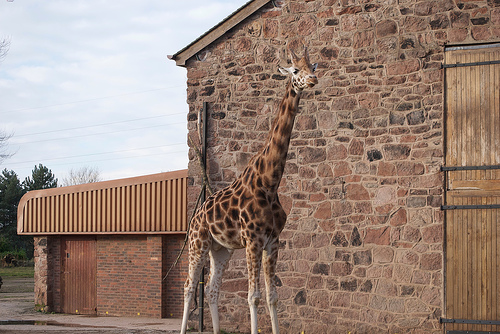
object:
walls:
[169, 0, 500, 334]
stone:
[353, 92, 382, 109]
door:
[440, 46, 499, 333]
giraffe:
[180, 45, 328, 334]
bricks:
[147, 309, 159, 312]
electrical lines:
[0, 162, 186, 189]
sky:
[0, 1, 249, 189]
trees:
[1, 130, 111, 268]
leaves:
[1, 164, 66, 266]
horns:
[286, 97, 299, 115]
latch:
[440, 162, 499, 175]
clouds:
[0, 0, 244, 187]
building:
[13, 0, 500, 334]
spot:
[289, 88, 298, 99]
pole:
[196, 100, 213, 333]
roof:
[167, 0, 265, 65]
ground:
[0, 281, 185, 334]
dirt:
[1, 285, 38, 295]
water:
[130, 321, 170, 328]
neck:
[236, 86, 300, 189]